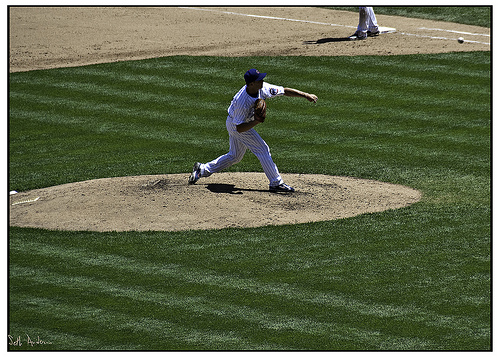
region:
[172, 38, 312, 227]
Baseball pitcher throwing ball.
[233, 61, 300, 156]
Baseball player wearing mitt on right hand.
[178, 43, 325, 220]
Baseball player wearing striped uniform.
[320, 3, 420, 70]
Baseball player standing at first base.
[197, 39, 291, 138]
Baseball player wearing blue hat with red letter.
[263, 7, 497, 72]
White painted lines on dirt.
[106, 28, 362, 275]
Baseball player standing on dirt mound.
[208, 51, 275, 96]
man has blue cap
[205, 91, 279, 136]
man has white shirt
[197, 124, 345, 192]
man has white pants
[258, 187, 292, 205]
man has blue shoes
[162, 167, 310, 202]
man extending from rubber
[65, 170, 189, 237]
brown dirt on mound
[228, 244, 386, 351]
green grass on infield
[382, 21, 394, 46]
first base is white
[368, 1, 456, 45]
white line on dirt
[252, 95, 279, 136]
man has brown glove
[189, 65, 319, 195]
A Chicago Cubs pitcher throws a baseball.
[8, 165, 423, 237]
Pitcher's mound.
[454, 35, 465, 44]
Baseball pitch heading to home plate.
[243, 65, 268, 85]
Blue Chicago Cubs baseball cap.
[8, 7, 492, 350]
Baseball field.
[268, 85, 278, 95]
Chicago Cubs logo on uniform sleeve.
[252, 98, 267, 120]
Brown leather baseball glove.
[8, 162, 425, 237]
Clay pitcher's mound.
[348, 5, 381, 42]
Baseball player standing on a base.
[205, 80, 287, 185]
White Chicago Cubs uniform with blue stripes.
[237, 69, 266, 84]
Blue cap on player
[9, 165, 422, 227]
A dirt pitcher's mound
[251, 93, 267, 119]
Glove on player's hand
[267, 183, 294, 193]
Black shoe on pitcher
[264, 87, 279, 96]
Decal on pitcher's shirt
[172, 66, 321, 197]
Pitcher throwing a baseball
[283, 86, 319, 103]
Left arm on pitcher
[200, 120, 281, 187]
White baseball uniform pants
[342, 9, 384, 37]
Legs of player on first base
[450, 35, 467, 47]
Baseball flying through the air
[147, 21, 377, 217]
this is a man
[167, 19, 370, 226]
the man is a baseball player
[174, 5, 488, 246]
player threw a ball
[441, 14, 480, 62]
baseball in the air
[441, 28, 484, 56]
the baseball is white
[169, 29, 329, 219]
player wearing white uniform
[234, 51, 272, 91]
player wearing a blue hat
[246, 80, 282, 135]
player with catchers mitt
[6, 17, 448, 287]
player standing on pitchers mound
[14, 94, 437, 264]
pitchers mound is dirt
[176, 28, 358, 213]
man is a baseball player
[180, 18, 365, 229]
man threw a ball